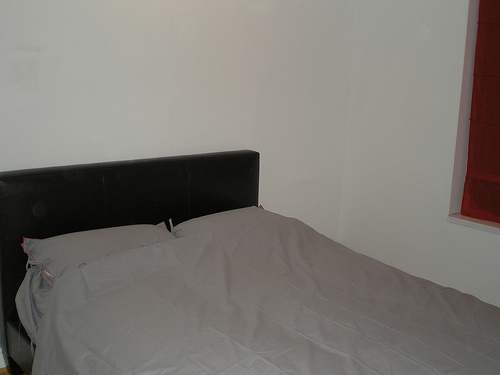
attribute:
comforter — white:
[5, 197, 499, 372]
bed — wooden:
[0, 145, 499, 373]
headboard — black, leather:
[3, 146, 265, 329]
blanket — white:
[155, 241, 230, 293]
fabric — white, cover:
[205, 267, 325, 338]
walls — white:
[1, 1, 355, 246]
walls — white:
[336, 0, 499, 308]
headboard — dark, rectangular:
[7, 148, 264, 259]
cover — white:
[30, 213, 499, 373]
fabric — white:
[6, 225, 398, 373]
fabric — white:
[29, 240, 494, 373]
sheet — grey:
[38, 196, 498, 372]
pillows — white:
[32, 199, 274, 260]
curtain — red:
[462, 31, 499, 223]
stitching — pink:
[15, 236, 51, 288]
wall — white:
[4, 5, 497, 300]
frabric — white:
[127, 251, 285, 323]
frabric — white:
[271, 287, 409, 372]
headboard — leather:
[49, 141, 258, 229]